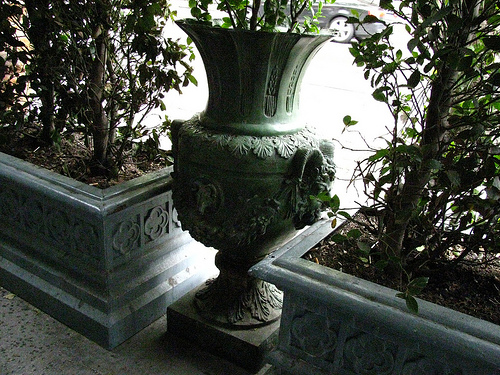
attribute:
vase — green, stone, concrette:
[171, 14, 340, 331]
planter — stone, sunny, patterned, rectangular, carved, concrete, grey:
[2, 134, 205, 354]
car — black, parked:
[239, 0, 395, 43]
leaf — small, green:
[404, 290, 419, 316]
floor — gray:
[1, 286, 275, 374]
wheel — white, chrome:
[327, 16, 356, 45]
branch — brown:
[115, 41, 134, 162]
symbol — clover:
[110, 218, 141, 256]